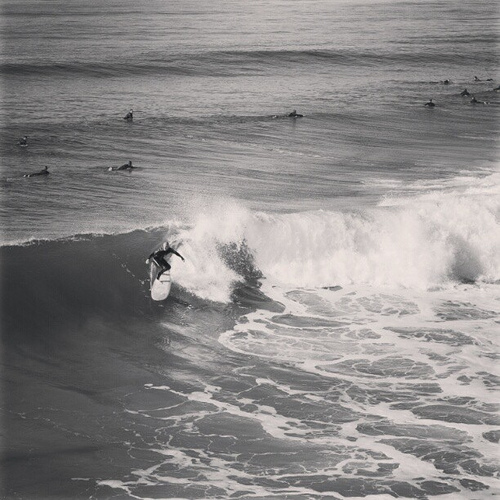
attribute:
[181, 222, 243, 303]
wave — breaking 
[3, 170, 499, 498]
spray — White 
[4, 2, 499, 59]
sea — calm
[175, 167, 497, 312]
violent waters — Violent 